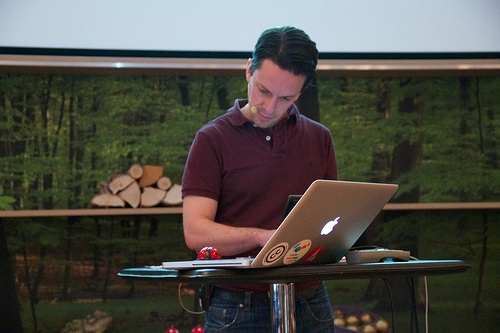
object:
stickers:
[262, 240, 323, 267]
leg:
[269, 283, 297, 333]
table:
[116, 259, 473, 333]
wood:
[91, 164, 183, 209]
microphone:
[250, 106, 257, 114]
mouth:
[257, 111, 273, 121]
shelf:
[0, 206, 184, 218]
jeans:
[200, 281, 337, 333]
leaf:
[459, 129, 478, 142]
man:
[180, 25, 337, 333]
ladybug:
[197, 247, 222, 260]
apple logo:
[320, 216, 341, 236]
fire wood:
[163, 183, 183, 206]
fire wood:
[138, 165, 163, 188]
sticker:
[262, 242, 289, 267]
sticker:
[283, 239, 312, 265]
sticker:
[303, 246, 324, 265]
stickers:
[262, 239, 311, 266]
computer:
[162, 180, 399, 270]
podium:
[116, 259, 470, 285]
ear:
[246, 59, 253, 81]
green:
[20, 231, 120, 308]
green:
[435, 217, 494, 313]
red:
[197, 246, 221, 259]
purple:
[207, 128, 304, 174]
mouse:
[189, 240, 219, 263]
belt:
[214, 283, 319, 304]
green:
[359, 87, 498, 223]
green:
[10, 74, 143, 168]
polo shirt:
[180, 98, 337, 291]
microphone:
[251, 106, 257, 113]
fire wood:
[91, 192, 126, 208]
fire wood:
[108, 174, 135, 194]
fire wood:
[118, 181, 142, 209]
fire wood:
[129, 164, 144, 179]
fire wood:
[157, 177, 172, 190]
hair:
[247, 25, 318, 94]